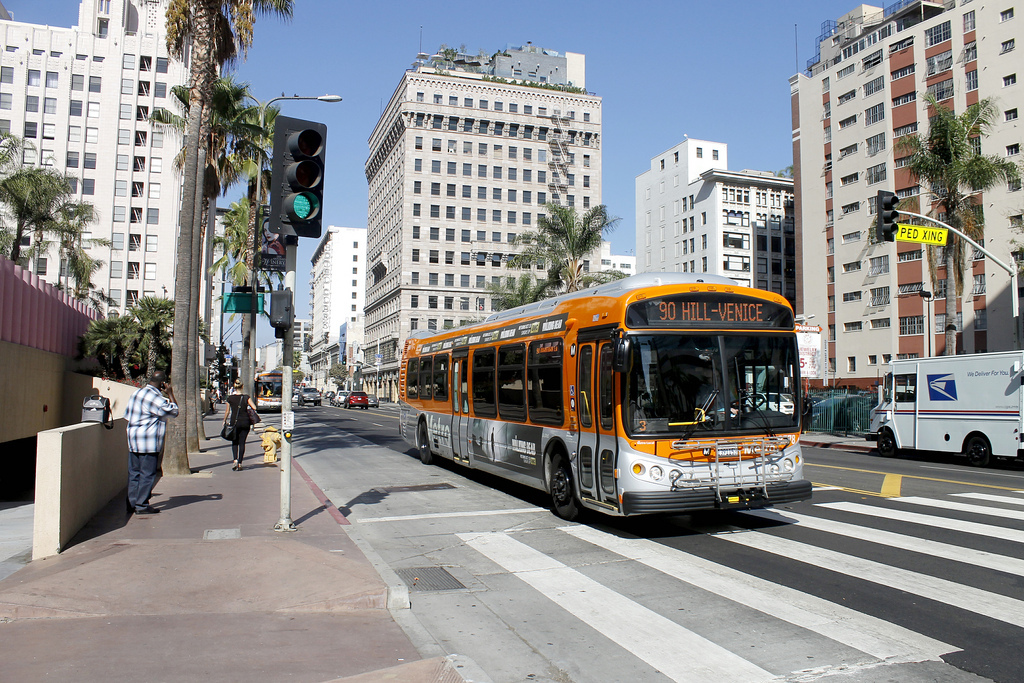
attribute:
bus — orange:
[369, 264, 830, 537]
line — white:
[456, 526, 772, 678]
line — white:
[558, 521, 956, 664]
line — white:
[712, 521, 1022, 619]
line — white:
[824, 495, 1023, 543]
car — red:
[344, 387, 373, 411]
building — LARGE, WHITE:
[359, 39, 608, 409]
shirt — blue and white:
[124, 380, 174, 454]